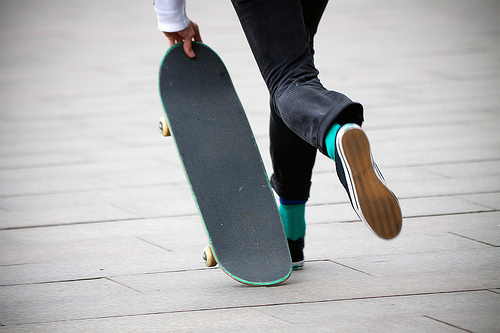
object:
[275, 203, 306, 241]
sock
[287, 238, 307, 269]
sneaker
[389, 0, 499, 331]
blocks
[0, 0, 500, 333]
sidewalk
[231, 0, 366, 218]
pants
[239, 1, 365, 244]
legs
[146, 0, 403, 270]
person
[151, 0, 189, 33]
shirt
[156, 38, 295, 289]
skateboard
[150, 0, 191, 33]
wrist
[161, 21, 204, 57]
left hand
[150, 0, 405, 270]
skateboarder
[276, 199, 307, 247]
socks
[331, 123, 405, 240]
foot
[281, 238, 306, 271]
shoe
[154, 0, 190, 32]
pillows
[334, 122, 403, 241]
sneaker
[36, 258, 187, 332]
cement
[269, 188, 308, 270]
foot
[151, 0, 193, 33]
shirt sleeve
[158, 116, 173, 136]
yellow wheel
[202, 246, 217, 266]
yellow wheel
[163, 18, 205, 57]
hand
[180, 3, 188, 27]
seam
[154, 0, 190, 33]
cuff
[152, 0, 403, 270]
person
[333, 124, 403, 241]
shoe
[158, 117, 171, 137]
wheel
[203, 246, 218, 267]
wheel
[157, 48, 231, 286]
rim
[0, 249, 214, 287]
crack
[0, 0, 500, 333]
brick ground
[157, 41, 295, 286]
trim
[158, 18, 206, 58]
hand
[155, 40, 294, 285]
board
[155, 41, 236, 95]
top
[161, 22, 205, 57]
hand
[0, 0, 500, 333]
ground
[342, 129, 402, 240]
sole